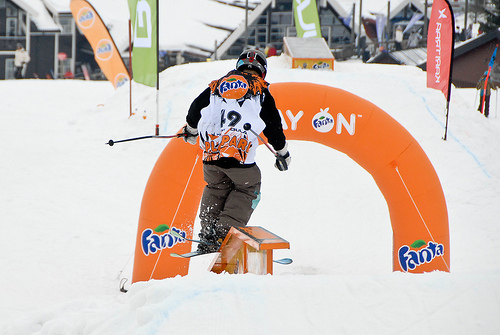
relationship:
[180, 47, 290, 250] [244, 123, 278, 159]
person holding ski pole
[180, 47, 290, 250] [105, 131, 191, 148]
person holding ski pole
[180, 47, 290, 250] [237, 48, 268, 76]
person wearing helmet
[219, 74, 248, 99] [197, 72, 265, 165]
advertisement on back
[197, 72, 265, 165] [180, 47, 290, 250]
back of person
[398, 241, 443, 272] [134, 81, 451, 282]
logo on inflatable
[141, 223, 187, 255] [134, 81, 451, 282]
logo on inflatable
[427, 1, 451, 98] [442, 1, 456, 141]
banner on pole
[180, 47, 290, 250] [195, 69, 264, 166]
person wearing vest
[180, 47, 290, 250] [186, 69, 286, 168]
person wearing jacket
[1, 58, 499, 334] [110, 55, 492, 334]
snow on slope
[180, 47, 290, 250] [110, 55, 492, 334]
person sliding down slope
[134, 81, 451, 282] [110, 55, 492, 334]
inflatable on slope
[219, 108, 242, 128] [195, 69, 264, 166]
number on vest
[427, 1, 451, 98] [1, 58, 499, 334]
banner in snow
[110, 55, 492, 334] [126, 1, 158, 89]
slope behind sign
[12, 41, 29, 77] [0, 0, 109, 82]
person in front of chalet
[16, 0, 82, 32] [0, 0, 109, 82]
roof of chalet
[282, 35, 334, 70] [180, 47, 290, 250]
jump in front of person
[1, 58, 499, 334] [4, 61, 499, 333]
snow on ground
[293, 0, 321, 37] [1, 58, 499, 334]
flag in snow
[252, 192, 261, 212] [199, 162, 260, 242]
patch on pants